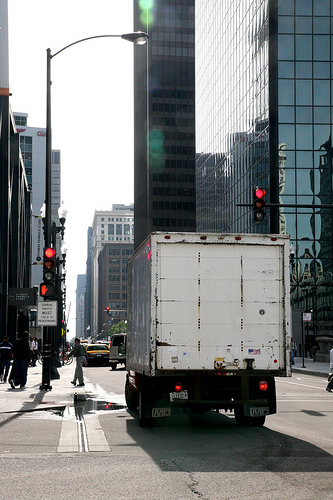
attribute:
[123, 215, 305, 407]
truck — white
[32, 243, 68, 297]
traffic light — red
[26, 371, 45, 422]
sidewalk — paved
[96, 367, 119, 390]
street — paved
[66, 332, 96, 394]
man — walking